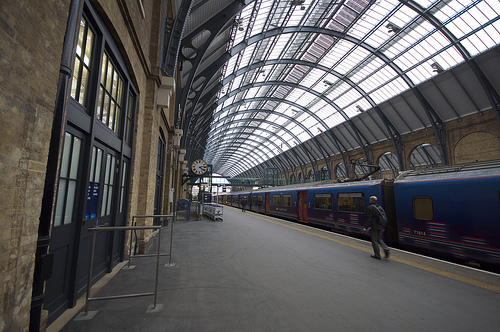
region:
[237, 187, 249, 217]
a man waiting on the train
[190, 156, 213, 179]
a clock hanging from the wall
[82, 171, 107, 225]
a sign in the window of the door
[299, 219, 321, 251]
a yellow line on the ground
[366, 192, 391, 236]
a man with a book bag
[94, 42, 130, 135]
windows above the door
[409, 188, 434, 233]
a window on the train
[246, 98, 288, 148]
windows in the roof of the building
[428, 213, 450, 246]
strips on the side of the train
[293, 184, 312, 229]
doors on the side of the train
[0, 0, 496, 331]
Brick and glass subway station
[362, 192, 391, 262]
Man walking on a subway platform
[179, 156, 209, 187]
Wall mounted white analog clock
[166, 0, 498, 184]
Glass and steel arched ceiling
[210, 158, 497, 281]
Blue subway train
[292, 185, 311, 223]
Red doors of a subway train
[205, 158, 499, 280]
Subway train in a station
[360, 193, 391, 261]
Man wearing a backpack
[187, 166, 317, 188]
Green metal skywalk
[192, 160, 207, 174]
Clock inside train station near ceiling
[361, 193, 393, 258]
Man in blue jacket walking next to train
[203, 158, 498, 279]
Blue train moving along the track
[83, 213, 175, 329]
Metal gates next to black doors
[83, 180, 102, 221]
Blue sign on the front of the door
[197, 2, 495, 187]
Glass ceiling on top of the train station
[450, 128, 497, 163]
Brick archway on the side of the train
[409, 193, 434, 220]
Window in the back of the train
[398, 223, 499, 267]
Stripes on the side of the train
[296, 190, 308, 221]
Red doors in the side of the train car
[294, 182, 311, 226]
doors on the train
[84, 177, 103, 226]
a sign on the door of the building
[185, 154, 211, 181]
a clock on the side of the wall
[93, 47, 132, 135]
windows above the door of the building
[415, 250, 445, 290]
a ywllow line on the ground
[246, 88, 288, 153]
windows in the roof of the building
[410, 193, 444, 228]
a window on the side of the train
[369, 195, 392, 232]
a man with a bookbag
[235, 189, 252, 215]
people waiting on the train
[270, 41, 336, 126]
windows in the roof of the building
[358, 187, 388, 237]
a man with a bookbag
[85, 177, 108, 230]
a sign on the door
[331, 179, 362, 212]
windoes on a train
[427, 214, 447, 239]
stripes on the side of the train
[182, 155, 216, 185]
a clock hanging from the wall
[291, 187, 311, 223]
doors on the train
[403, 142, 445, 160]
A window on a building.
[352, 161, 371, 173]
A window on a building.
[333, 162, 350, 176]
A window on a building.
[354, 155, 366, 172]
A window on a building.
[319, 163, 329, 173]
A window on a building.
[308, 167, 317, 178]
A window on a building.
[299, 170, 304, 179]
A window on a building.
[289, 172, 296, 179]
A window on a building.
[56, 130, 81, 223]
A window on a building.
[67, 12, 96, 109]
A window on a building.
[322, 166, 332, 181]
A window on a building.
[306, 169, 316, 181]
A window on a building.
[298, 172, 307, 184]
A window on a building.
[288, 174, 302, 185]
A window on a building.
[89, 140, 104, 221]
A window on a building.